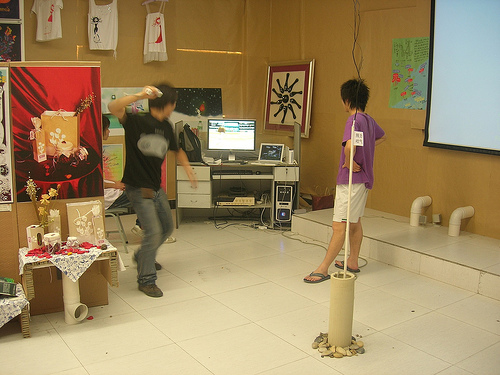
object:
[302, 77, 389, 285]
man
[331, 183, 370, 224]
shorts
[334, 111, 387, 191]
shirt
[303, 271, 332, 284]
sandals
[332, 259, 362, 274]
sandal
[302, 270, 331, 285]
sandal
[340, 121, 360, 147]
short sleeve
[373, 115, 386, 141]
short sleeve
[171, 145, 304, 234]
desk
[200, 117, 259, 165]
monitor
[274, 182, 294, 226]
tower pc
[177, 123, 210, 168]
backpack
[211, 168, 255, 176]
keyboard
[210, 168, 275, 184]
desk pull-out shelf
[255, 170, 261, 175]
mouse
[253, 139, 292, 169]
old terminal [?]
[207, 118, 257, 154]
screen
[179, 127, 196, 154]
grey trim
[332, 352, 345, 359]
rocks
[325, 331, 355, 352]
circle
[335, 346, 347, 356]
rock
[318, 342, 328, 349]
rock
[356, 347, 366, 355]
rock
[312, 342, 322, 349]
rock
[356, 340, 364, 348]
rock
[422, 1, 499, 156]
screen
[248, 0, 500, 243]
wall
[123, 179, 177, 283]
jeans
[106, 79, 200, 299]
man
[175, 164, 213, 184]
drawer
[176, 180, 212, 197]
drawer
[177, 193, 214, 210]
drawer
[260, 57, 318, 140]
picture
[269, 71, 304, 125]
array of rays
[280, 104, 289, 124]
rays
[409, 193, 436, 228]
pipe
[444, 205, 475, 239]
pipes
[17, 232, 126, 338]
table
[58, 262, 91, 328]
base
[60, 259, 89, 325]
pipe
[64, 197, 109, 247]
lively items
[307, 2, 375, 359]
folk art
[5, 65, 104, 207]
picture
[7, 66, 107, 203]
still life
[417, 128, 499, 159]
wrinkle at bottom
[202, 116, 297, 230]
game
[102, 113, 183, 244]
man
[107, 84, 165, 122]
arm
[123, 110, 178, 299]
body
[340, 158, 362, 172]
hand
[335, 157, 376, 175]
waist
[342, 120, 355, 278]
pole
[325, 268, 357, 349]
tube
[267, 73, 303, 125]
swirl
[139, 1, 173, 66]
garment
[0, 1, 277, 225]
wall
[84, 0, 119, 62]
garment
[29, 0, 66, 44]
garment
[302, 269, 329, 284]
foot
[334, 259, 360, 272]
foot